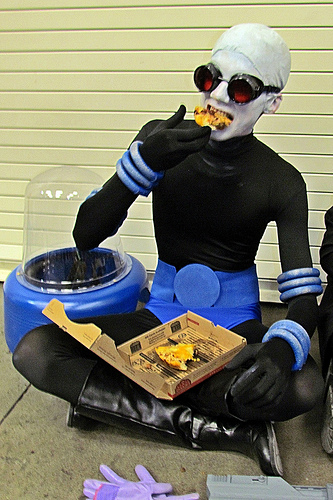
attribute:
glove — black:
[137, 103, 214, 176]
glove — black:
[223, 333, 298, 411]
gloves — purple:
[79, 464, 202, 499]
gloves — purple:
[70, 443, 201, 498]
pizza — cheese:
[149, 338, 196, 367]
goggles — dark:
[191, 61, 281, 106]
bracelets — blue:
[110, 136, 174, 201]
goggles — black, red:
[186, 60, 292, 107]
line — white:
[0, 1, 332, 12]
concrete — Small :
[14, 408, 62, 483]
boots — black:
[228, 400, 298, 479]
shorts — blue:
[149, 261, 260, 331]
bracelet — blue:
[111, 162, 151, 201]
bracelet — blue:
[121, 147, 155, 191]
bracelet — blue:
[128, 137, 165, 180]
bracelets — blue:
[115, 140, 165, 196]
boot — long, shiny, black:
[87, 371, 286, 453]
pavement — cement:
[24, 413, 119, 476]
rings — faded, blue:
[255, 268, 316, 309]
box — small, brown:
[124, 306, 246, 399]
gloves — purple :
[76, 452, 175, 498]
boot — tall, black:
[61, 370, 296, 462]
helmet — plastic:
[5, 162, 151, 358]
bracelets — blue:
[258, 315, 313, 369]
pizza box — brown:
[40, 292, 247, 398]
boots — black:
[73, 367, 259, 451]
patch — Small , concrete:
[19, 383, 114, 472]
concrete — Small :
[0, 280, 325, 497]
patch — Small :
[135, 448, 241, 471]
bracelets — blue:
[269, 260, 330, 309]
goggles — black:
[181, 62, 316, 108]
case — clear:
[17, 165, 131, 295]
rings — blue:
[278, 265, 320, 301]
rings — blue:
[111, 137, 161, 198]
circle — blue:
[169, 260, 228, 319]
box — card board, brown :
[38, 293, 251, 404]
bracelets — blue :
[118, 139, 160, 201]